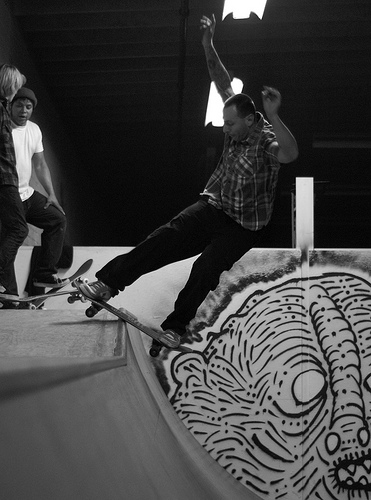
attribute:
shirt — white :
[7, 115, 44, 204]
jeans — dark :
[95, 192, 247, 330]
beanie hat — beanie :
[12, 86, 35, 99]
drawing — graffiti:
[169, 270, 369, 498]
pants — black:
[82, 190, 268, 334]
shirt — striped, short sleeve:
[206, 120, 304, 237]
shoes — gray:
[77, 278, 181, 350]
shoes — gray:
[0, 274, 67, 307]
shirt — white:
[10, 112, 47, 205]